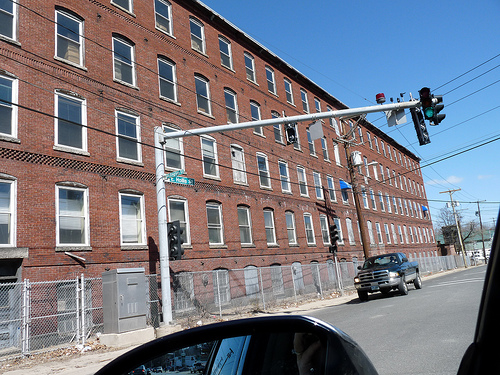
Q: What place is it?
A: It is a sidewalk.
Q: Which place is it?
A: It is a sidewalk.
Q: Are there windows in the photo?
A: Yes, there is a window.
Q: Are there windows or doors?
A: Yes, there is a window.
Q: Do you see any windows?
A: Yes, there is a window.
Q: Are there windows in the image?
A: Yes, there is a window.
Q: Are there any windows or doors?
A: Yes, there is a window.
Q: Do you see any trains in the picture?
A: No, there are no trains.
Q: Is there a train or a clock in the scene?
A: No, there are no trains or clocks.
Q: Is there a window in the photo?
A: Yes, there is a window.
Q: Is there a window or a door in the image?
A: Yes, there is a window.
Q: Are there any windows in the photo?
A: Yes, there is a window.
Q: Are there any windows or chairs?
A: Yes, there is a window.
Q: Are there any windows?
A: Yes, there is a window.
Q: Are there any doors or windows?
A: Yes, there is a window.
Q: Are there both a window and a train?
A: No, there is a window but no trains.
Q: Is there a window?
A: Yes, there is a window.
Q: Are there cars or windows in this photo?
A: Yes, there is a window.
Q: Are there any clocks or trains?
A: No, there are no clocks or trains.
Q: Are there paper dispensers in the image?
A: No, there are no paper dispensers.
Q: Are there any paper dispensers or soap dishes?
A: No, there are no paper dispensers or soap dishes.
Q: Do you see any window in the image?
A: Yes, there is a window.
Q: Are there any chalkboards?
A: No, there are no chalkboards.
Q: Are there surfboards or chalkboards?
A: No, there are no chalkboards or surfboards.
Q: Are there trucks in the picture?
A: Yes, there is a truck.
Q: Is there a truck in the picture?
A: Yes, there is a truck.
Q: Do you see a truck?
A: Yes, there is a truck.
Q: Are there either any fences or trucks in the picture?
A: Yes, there is a truck.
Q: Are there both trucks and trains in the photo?
A: No, there is a truck but no trains.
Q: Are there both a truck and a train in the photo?
A: No, there is a truck but no trains.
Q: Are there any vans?
A: No, there are no vans.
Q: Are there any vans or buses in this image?
A: No, there are no vans or buses.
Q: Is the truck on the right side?
A: Yes, the truck is on the right of the image.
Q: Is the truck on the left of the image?
A: No, the truck is on the right of the image.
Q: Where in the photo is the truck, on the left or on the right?
A: The truck is on the right of the image.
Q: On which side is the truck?
A: The truck is on the right of the image.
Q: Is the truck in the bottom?
A: Yes, the truck is in the bottom of the image.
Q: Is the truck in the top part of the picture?
A: No, the truck is in the bottom of the image.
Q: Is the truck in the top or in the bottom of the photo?
A: The truck is in the bottom of the image.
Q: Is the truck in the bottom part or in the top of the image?
A: The truck is in the bottom of the image.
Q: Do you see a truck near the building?
A: Yes, there is a truck near the building.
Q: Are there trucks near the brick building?
A: Yes, there is a truck near the building.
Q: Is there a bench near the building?
A: No, there is a truck near the building.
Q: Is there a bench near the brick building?
A: No, there is a truck near the building.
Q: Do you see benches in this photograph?
A: No, there are no benches.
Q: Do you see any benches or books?
A: No, there are no benches or books.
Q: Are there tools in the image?
A: No, there are no tools.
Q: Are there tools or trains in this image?
A: No, there are no tools or trains.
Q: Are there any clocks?
A: No, there are no clocks.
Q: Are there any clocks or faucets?
A: No, there are no clocks or faucets.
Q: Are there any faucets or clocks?
A: No, there are no clocks or faucets.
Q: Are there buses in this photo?
A: No, there are no buses.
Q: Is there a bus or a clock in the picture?
A: No, there are no buses or clocks.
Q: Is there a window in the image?
A: Yes, there is a window.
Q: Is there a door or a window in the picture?
A: Yes, there is a window.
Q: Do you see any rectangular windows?
A: Yes, there is a rectangular window.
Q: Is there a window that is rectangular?
A: Yes, there is a window that is rectangular.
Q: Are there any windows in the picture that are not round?
A: Yes, there is a rectangular window.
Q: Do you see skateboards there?
A: No, there are no skateboards.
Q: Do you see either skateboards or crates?
A: No, there are no skateboards or crates.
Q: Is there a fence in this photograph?
A: Yes, there is a fence.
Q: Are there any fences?
A: Yes, there is a fence.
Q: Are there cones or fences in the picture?
A: Yes, there is a fence.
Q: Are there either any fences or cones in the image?
A: Yes, there is a fence.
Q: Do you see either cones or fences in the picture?
A: Yes, there is a fence.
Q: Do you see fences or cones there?
A: Yes, there is a fence.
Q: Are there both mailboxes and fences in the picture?
A: No, there is a fence but no mailboxes.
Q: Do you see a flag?
A: No, there are no flags.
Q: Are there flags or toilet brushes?
A: No, there are no flags or toilet brushes.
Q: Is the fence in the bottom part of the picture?
A: Yes, the fence is in the bottom of the image.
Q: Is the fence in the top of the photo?
A: No, the fence is in the bottom of the image.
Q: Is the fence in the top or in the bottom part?
A: The fence is in the bottom of the image.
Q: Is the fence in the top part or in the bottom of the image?
A: The fence is in the bottom of the image.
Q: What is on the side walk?
A: The fence is on the side walk.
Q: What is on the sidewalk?
A: The fence is on the side walk.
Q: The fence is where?
A: The fence is on the sidewalk.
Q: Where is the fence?
A: The fence is on the sidewalk.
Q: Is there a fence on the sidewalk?
A: Yes, there is a fence on the sidewalk.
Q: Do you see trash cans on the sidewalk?
A: No, there is a fence on the sidewalk.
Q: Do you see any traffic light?
A: Yes, there is a traffic light.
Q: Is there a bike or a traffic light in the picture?
A: Yes, there is a traffic light.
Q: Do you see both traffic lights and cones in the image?
A: No, there is a traffic light but no cones.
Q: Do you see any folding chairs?
A: No, there are no folding chairs.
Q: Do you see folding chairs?
A: No, there are no folding chairs.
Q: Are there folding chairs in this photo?
A: No, there are no folding chairs.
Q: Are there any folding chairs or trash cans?
A: No, there are no folding chairs or trash cans.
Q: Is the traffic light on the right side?
A: Yes, the traffic light is on the right of the image.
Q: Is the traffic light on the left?
A: No, the traffic light is on the right of the image.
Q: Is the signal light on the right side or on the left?
A: The signal light is on the right of the image.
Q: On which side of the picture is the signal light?
A: The signal light is on the right of the image.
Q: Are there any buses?
A: No, there are no buses.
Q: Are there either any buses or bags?
A: No, there are no buses or bags.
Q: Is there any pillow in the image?
A: No, there are no pillows.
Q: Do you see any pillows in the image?
A: No, there are no pillows.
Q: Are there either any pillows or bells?
A: No, there are no pillows or bells.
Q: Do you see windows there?
A: Yes, there is a window.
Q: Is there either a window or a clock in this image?
A: Yes, there is a window.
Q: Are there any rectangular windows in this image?
A: Yes, there is a rectangular window.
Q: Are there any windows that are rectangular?
A: Yes, there is a window that is rectangular.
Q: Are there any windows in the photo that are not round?
A: Yes, there is a rectangular window.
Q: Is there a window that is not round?
A: Yes, there is a rectangular window.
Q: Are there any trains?
A: No, there are no trains.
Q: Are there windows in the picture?
A: Yes, there is a window.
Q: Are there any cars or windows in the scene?
A: Yes, there is a window.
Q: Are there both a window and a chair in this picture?
A: No, there is a window but no chairs.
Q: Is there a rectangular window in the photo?
A: Yes, there is a rectangular window.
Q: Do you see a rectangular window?
A: Yes, there is a rectangular window.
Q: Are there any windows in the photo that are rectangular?
A: Yes, there is a window that is rectangular.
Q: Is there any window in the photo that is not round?
A: Yes, there is a rectangular window.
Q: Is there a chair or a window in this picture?
A: Yes, there is a window.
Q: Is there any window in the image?
A: Yes, there is a window.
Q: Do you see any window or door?
A: Yes, there is a window.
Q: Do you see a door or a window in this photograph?
A: Yes, there is a window.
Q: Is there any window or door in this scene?
A: Yes, there is a window.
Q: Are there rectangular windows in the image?
A: Yes, there is a rectangular window.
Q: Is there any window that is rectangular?
A: Yes, there is a window that is rectangular.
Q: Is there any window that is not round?
A: Yes, there is a rectangular window.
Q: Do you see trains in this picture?
A: No, there are no trains.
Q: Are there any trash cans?
A: No, there are no trash cans.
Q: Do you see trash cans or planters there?
A: No, there are no trash cans or planters.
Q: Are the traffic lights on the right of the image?
A: Yes, the traffic lights are on the right of the image.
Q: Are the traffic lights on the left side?
A: No, the traffic lights are on the right of the image.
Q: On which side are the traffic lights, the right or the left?
A: The traffic lights are on the right of the image.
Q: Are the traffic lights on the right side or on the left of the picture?
A: The traffic lights are on the right of the image.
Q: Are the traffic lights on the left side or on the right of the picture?
A: The traffic lights are on the right of the image.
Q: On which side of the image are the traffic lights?
A: The traffic lights are on the right of the image.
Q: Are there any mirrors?
A: Yes, there is a mirror.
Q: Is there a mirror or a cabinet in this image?
A: Yes, there is a mirror.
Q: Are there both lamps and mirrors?
A: No, there is a mirror but no lamps.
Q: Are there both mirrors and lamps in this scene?
A: No, there is a mirror but no lamps.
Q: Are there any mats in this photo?
A: No, there are no mats.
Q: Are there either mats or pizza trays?
A: No, there are no mats or pizza trays.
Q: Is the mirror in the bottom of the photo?
A: Yes, the mirror is in the bottom of the image.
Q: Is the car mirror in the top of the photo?
A: No, the mirror is in the bottom of the image.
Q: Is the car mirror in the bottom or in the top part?
A: The mirror is in the bottom of the image.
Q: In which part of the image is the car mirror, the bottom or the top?
A: The mirror is in the bottom of the image.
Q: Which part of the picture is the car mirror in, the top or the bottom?
A: The mirror is in the bottom of the image.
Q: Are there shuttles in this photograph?
A: No, there are no shuttles.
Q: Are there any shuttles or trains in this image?
A: No, there are no shuttles or trains.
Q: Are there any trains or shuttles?
A: No, there are no shuttles or trains.